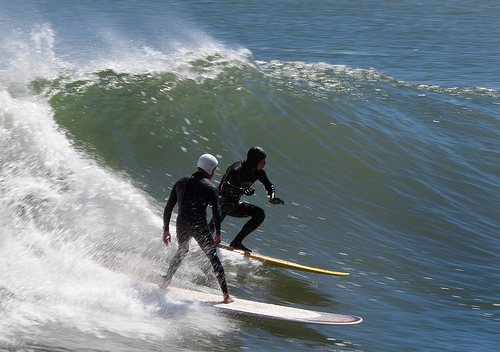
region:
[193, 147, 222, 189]
THE MAN IS WEARING A WHITE SWIM CAP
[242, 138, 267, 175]
THE MAN IS WEARING A BLACK SWIMCAP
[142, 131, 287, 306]
THE MEN ARE WET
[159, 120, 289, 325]
THE MEN ARE SURFING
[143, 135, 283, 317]
THE MEN ARE WEARING BLACK WETSUITS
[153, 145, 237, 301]
THE MAN IS ON A SURFBOARD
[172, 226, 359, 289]
THE SURFBOARD IS YELLOW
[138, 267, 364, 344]
THE SURFBOARD IS WHITE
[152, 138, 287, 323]
THE MEN ARE RIDING A WAVE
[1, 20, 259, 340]
THE WAVE IS BREAKING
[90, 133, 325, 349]
a man is surfing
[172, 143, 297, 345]
a man is surfing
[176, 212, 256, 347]
a man is surfing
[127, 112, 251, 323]
a man is surfing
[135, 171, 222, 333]
a man is surfing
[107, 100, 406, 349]
two person in water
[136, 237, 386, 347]
machine used to skat in water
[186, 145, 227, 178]
a white cap wearing by person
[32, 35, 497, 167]
a big flow of water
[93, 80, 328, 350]
two men wearing black dress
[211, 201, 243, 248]
hand of the person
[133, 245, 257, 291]
leg of the person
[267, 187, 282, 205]
gloves wearing by person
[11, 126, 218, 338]
highly disturbed water flow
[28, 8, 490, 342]
beautiful view of water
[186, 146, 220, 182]
man wearing helmet on head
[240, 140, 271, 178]
man wearing helmet on head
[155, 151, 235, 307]
surfer wearing black swimming combination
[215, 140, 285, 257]
surfer wearing black swimming combination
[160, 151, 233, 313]
man is surfing the wave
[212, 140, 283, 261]
man is surfing the wave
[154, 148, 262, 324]
man riding white surfboard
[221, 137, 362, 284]
man riding yellow surfboard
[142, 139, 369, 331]
two persons riding surfboards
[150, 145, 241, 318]
surfer is riding board barefeet